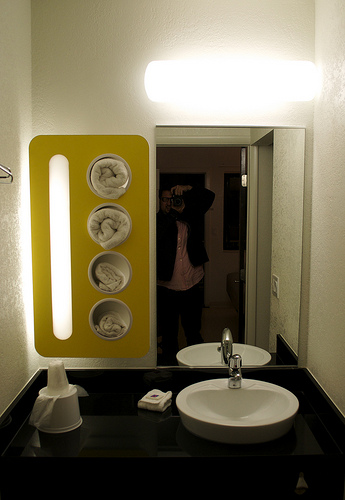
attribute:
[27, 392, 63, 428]
tissue — white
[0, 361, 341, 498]
counter — black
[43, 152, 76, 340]
light — tubular, long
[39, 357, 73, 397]
cup — plastic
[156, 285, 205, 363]
pants — black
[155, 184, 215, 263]
reflection — man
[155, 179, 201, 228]
man — holding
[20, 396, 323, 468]
table — black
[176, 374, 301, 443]
sink — white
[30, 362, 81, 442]
cups — plastic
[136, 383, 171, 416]
towel — folded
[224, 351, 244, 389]
faucet — metal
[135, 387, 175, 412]
washcloth — white